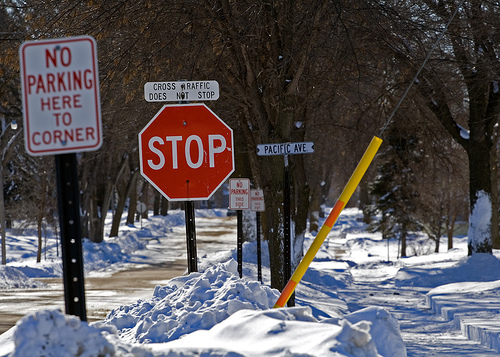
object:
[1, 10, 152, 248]
tree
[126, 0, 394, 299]
tree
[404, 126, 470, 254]
tree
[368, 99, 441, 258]
tree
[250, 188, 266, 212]
sign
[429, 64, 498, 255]
trunk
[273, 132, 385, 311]
pole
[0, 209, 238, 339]
road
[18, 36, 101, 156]
letters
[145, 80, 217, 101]
parking signs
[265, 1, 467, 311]
wire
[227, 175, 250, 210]
sign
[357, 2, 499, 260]
tree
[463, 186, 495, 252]
snow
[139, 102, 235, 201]
letter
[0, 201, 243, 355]
pavement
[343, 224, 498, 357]
sidewalk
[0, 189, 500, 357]
snow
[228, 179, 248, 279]
post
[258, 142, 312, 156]
pacific ave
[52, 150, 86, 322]
pole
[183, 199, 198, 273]
pole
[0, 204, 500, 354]
ground